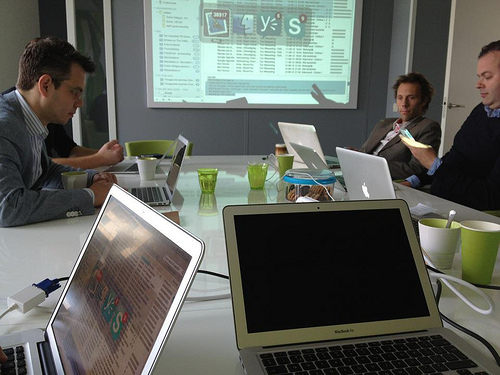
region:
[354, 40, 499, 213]
two men sitting at a table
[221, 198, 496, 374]
a laptop on a table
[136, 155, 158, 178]
a white cup on a table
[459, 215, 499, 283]
a green cup on a table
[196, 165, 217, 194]
a green glass on a table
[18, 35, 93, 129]
a man with brown hair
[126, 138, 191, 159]
green seat of a chair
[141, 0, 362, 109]
a white screen on a wall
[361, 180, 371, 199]
a white apple logo on a laptop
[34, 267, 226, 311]
a blue plug and wire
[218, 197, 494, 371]
AN OPEN LAPTOP COMPUTER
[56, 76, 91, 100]
A PAIR OF GLASSES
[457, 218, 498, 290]
A GREEN CUP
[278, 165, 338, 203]
A TIN OF COOKIES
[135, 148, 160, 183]
A WHITE CUP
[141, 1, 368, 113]
A SCREEN PROJECTION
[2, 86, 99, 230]
A GRAY SUIT COAT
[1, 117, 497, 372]
FIVE LAPTOP COMPUTERS ON A TABLE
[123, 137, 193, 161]
THE BACK OF A GREEN CHAIR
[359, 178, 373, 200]
THE APPLE LOGO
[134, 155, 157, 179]
coffee mug on table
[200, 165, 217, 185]
green cup on the table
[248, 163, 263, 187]
green cup on table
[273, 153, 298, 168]
green coffee mug on table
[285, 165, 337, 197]
container of cookies on table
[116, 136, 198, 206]
laptop on the table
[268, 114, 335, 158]
laptop on the table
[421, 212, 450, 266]
coffee mug on table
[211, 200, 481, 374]
laptop on the table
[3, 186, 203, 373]
laptop on table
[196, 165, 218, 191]
a green glass on the table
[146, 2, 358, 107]
a projection screen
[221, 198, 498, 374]
a laptop on the table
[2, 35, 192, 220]
a man looking at his laptop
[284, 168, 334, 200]
a bowl of cookies on the table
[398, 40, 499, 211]
a man looking down at his phone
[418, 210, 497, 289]
two green cups on the table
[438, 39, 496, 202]
a man wearing a black sweater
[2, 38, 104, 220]
a man wearing glasses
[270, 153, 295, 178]
a green coffee mug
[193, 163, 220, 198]
green glass on a table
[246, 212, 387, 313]
black screen of a laptop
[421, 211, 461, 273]
glass with a utensil in it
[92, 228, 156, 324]
reflection on a lap top screen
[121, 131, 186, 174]
green back of an office chair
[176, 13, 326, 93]
projector screen illuminated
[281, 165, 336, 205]
tupperware full of cookies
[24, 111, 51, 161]
striped shirt on a man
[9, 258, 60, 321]
power cord plugged in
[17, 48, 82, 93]
short hair on a man